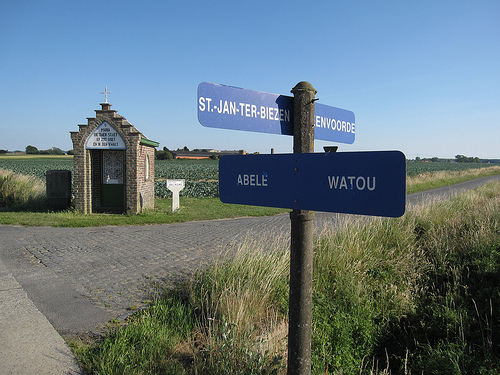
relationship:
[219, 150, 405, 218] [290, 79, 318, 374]
sign on pole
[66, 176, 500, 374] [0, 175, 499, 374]
grass by road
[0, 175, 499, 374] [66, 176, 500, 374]
road between grass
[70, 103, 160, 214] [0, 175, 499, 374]
building by road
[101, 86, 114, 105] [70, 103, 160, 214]
cross on building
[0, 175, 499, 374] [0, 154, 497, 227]
road by field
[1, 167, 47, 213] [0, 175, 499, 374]
bush by road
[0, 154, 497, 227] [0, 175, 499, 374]
field near road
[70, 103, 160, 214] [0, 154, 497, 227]
building by field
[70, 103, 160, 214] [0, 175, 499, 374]
building near road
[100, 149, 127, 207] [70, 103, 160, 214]
door on building